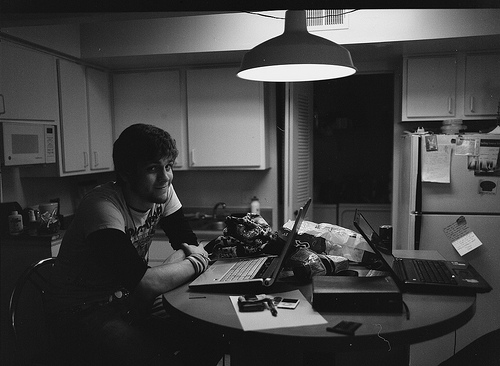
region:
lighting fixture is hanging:
[234, 7, 435, 153]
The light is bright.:
[227, 32, 380, 99]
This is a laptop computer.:
[186, 201, 313, 304]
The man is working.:
[63, 124, 210, 307]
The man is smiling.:
[61, 116, 208, 298]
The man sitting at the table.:
[35, 94, 205, 313]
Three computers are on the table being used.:
[168, 185, 498, 330]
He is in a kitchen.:
[15, 37, 498, 360]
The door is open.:
[261, 69, 413, 250]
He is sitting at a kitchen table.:
[39, 107, 496, 346]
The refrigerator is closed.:
[393, 119, 497, 364]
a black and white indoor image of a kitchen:
[0, 0, 498, 364]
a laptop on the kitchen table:
[187, 197, 312, 290]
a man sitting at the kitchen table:
[43, 122, 209, 364]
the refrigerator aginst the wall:
[408, 132, 498, 248]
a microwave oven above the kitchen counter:
[1, 119, 56, 168]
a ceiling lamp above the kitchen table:
[237, 9, 355, 81]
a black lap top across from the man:
[353, 211, 493, 293]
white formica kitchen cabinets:
[0, 36, 269, 168]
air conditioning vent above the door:
[306, 11, 349, 31]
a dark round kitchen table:
[163, 292, 472, 350]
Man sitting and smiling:
[43, 118, 216, 348]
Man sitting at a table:
[50, 115, 437, 363]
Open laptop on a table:
[186, 197, 318, 296]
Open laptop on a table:
[341, 202, 493, 304]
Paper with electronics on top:
[226, 288, 328, 338]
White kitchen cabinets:
[56, 97, 278, 185]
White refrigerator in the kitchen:
[403, 125, 498, 305]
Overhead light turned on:
[224, 2, 368, 97]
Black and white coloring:
[9, 5, 460, 361]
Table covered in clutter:
[198, 207, 484, 345]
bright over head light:
[227, 16, 397, 94]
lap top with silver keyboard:
[183, 197, 316, 301]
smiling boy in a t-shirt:
[31, 107, 214, 353]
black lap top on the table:
[351, 192, 491, 316]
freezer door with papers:
[398, 127, 498, 220]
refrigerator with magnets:
[399, 123, 499, 350]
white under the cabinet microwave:
[2, 115, 61, 174]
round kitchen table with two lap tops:
[168, 189, 486, 349]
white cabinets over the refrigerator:
[401, 57, 497, 122]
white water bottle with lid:
[248, 195, 264, 222]